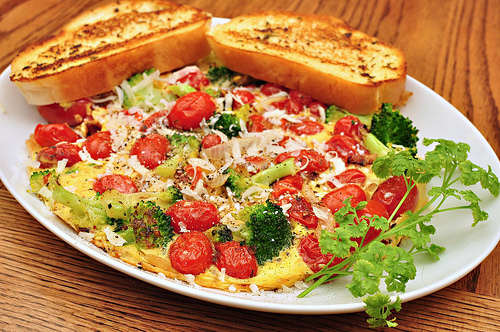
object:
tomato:
[166, 90, 217, 130]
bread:
[203, 9, 407, 116]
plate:
[425, 114, 460, 136]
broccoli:
[369, 102, 419, 153]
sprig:
[391, 145, 481, 244]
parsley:
[297, 218, 420, 297]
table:
[414, 8, 483, 62]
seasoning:
[106, 22, 135, 47]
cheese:
[245, 104, 282, 149]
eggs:
[265, 260, 298, 283]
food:
[9, 0, 499, 328]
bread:
[9, 0, 213, 106]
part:
[1, 107, 29, 120]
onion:
[188, 140, 305, 149]